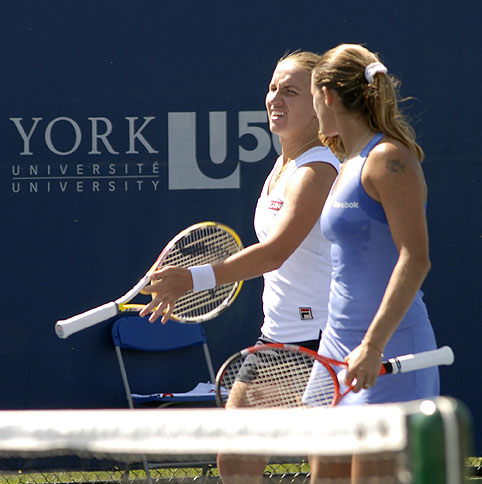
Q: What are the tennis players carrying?
A: Tennis rackets.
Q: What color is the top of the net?
A: White.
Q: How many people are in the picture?
A: Two.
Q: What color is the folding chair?
A: Blue.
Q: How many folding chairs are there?
A: One.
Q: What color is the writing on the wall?
A: White.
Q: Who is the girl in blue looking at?
A: The girl in white.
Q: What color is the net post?
A: Green.